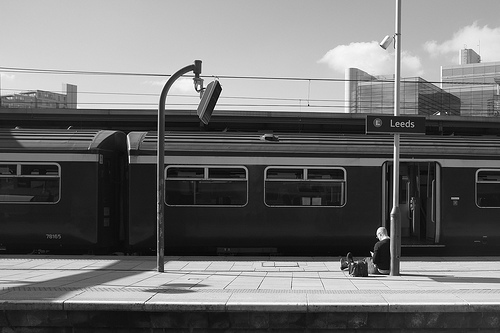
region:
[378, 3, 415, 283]
post on sidewalk with light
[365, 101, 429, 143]
sign with white writing says leeds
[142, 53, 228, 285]
pole with TV attatched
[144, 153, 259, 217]
three pane window in train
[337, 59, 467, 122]
tall building behind train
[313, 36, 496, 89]
a few clouds in the sky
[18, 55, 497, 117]
wires above the train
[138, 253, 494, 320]
sidewalk has large square tiles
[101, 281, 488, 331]
platform drops off here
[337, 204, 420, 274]
man sitting against pole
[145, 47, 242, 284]
security light with a steel pole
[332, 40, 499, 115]
two large buildings in the background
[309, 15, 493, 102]
large white fluffy clouds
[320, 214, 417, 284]
man sitting under a light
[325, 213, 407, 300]
man sitting beside a briefcase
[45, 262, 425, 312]
sidewalk with lots of cracks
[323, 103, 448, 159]
street sign with the letter l on it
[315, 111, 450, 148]
street sign with the letter e on it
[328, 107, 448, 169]
street sign with the letter d on it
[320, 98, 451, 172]
street sign with the letter s on it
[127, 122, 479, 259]
the train on the platform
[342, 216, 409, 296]
a man sitting on the platform with bags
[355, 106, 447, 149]
the sign boards used to show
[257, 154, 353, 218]
the windows of a train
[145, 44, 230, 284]
the pole with a tv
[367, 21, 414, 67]
the cctv cam attached on the pole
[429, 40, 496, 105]
the buildings beside the railway station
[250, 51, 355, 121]
the electrified power lines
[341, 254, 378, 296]
the black color bag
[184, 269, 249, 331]
the platform in the railway station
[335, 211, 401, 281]
A man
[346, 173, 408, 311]
A man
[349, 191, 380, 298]
A man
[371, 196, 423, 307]
A man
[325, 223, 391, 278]
person sitting on sidewalk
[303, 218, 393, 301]
black bag sitting beside person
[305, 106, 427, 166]
street sign that says leeds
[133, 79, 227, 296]
large solar light on pole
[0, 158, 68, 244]
window on a bus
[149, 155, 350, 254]
two windows on a bus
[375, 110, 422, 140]
white letters that spell leeds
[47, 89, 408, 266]
large bus and platform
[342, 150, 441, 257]
an open bus door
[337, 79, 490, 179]
buildings behind a bus